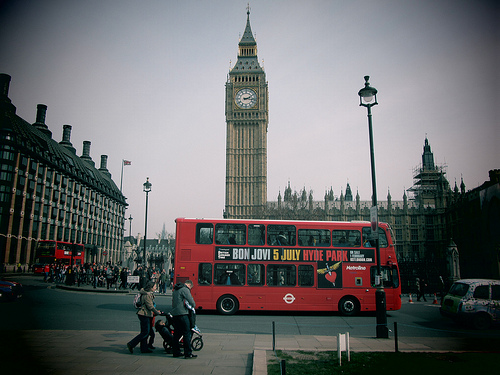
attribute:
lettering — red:
[303, 247, 350, 259]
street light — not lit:
[356, 68, 397, 344]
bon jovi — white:
[232, 244, 271, 261]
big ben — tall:
[217, 3, 277, 228]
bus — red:
[32, 235, 85, 276]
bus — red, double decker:
[171, 211, 404, 318]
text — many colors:
[232, 250, 347, 262]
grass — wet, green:
[276, 327, 477, 369]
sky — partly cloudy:
[63, 35, 200, 137]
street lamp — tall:
[357, 75, 393, 339]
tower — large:
[225, 4, 267, 219]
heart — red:
[322, 270, 338, 281]